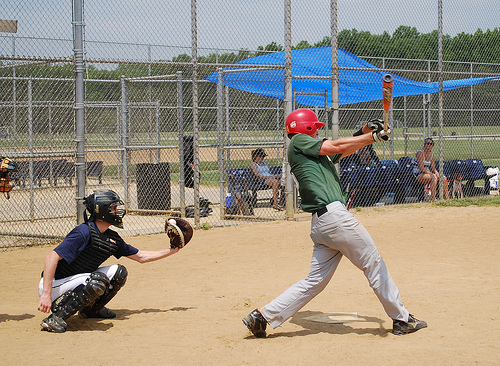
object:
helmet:
[79, 186, 129, 230]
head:
[81, 188, 120, 227]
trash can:
[133, 161, 173, 216]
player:
[241, 104, 426, 338]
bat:
[377, 74, 395, 139]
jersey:
[286, 132, 348, 215]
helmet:
[282, 106, 326, 140]